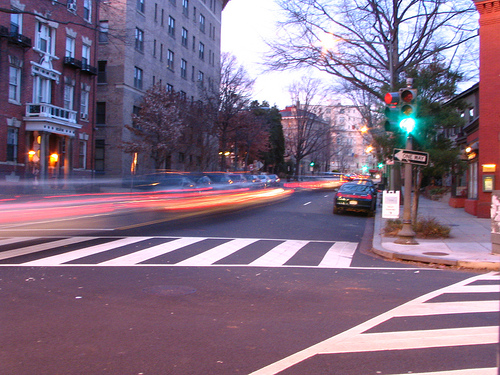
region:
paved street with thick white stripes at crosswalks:
[2, 183, 494, 373]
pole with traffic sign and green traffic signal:
[390, 70, 426, 242]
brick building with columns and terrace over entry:
[1, 1, 91, 187]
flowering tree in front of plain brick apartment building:
[95, 1, 215, 181]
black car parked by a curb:
[330, 170, 382, 220]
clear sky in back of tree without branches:
[222, 0, 473, 101]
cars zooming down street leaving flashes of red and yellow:
[0, 170, 345, 225]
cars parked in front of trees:
[131, 90, 283, 190]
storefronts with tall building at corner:
[420, 1, 495, 213]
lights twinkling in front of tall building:
[325, 100, 382, 177]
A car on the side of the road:
[334, 183, 374, 213]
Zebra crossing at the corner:
[0, 237, 373, 269]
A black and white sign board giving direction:
[393, 149, 429, 162]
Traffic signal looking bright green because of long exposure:
[383, 90, 415, 142]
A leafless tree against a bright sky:
[261, 3, 476, 201]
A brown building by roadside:
[96, 2, 220, 169]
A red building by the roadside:
[0, 0, 97, 179]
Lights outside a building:
[27, 137, 57, 174]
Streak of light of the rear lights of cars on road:
[0, 178, 344, 228]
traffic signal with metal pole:
[384, 84, 426, 142]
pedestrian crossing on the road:
[18, 218, 381, 273]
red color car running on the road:
[331, 169, 391, 220]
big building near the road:
[13, 29, 103, 146]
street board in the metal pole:
[393, 148, 429, 165]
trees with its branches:
[306, 9, 438, 86]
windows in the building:
[143, 18, 211, 98]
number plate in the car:
[346, 198, 358, 206]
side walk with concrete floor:
[434, 189, 476, 259]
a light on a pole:
[379, 55, 471, 222]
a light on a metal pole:
[389, 73, 437, 154]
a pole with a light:
[369, 61, 436, 172]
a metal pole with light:
[379, 76, 439, 218]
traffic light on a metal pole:
[372, 72, 434, 193]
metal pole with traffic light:
[367, 71, 449, 231]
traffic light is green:
[390, 89, 426, 149]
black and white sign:
[375, 133, 428, 180]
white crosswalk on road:
[2, 203, 407, 270]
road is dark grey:
[75, 268, 312, 365]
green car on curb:
[330, 170, 368, 211]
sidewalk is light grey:
[419, 196, 479, 256]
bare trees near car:
[313, 14, 438, 188]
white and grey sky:
[227, 14, 289, 89]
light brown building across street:
[88, 3, 223, 180]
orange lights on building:
[25, 135, 70, 183]